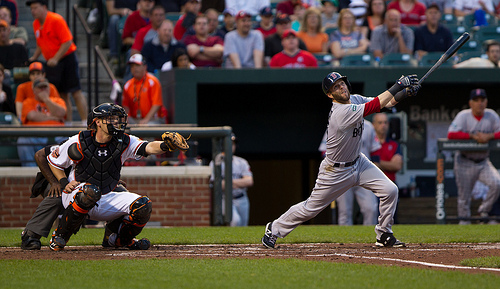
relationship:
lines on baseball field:
[107, 252, 331, 259] [1, 220, 499, 287]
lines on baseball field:
[346, 244, 496, 254] [1, 220, 499, 287]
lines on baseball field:
[335, 252, 498, 271] [1, 220, 499, 287]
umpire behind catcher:
[20, 140, 62, 249] [44, 102, 189, 249]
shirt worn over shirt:
[445, 110, 498, 163] [447, 112, 485, 142]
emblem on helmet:
[326, 72, 338, 82] [317, 69, 349, 81]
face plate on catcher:
[91, 101, 131, 143] [16, 99, 195, 254]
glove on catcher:
[158, 130, 190, 155] [16, 99, 195, 254]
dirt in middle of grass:
[3, 232, 498, 270] [1, 214, 498, 252]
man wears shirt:
[226, 8, 273, 72] [221, 25, 265, 65]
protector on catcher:
[74, 129, 131, 193] [44, 102, 189, 249]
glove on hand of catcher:
[148, 121, 188, 163] [36, 95, 190, 249]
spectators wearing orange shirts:
[19, 12, 168, 133] [15, 15, 183, 120]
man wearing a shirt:
[440, 73, 485, 223] [445, 108, 499, 160]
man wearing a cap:
[440, 73, 485, 223] [469, 83, 485, 103]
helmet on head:
[327, 67, 347, 85] [315, 60, 357, 110]